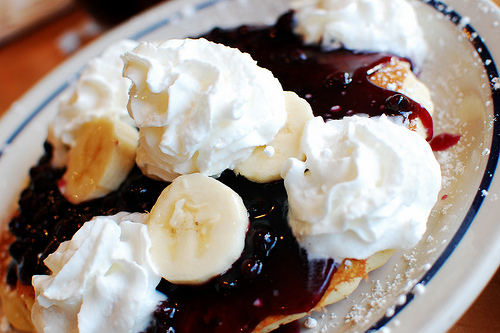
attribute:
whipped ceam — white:
[270, 127, 412, 227]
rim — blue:
[436, 2, 496, 90]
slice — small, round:
[128, 161, 276, 268]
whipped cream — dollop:
[108, 35, 283, 150]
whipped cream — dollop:
[282, 117, 436, 252]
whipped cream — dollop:
[288, 7, 420, 67]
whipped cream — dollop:
[28, 218, 171, 331]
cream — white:
[274, 97, 446, 250]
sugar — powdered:
[302, 232, 455, 332]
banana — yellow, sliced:
[62, 120, 135, 207]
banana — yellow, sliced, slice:
[146, 173, 246, 285]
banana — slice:
[144, 170, 252, 284]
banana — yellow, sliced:
[145, 178, 254, 283]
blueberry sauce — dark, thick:
[216, 182, 329, 322]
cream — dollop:
[109, 45, 259, 147]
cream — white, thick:
[238, 97, 276, 124]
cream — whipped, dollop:
[278, 103, 432, 257]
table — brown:
[0, 34, 60, 62]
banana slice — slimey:
[145, 173, 247, 282]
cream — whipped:
[280, 113, 441, 253]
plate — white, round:
[21, 14, 497, 308]